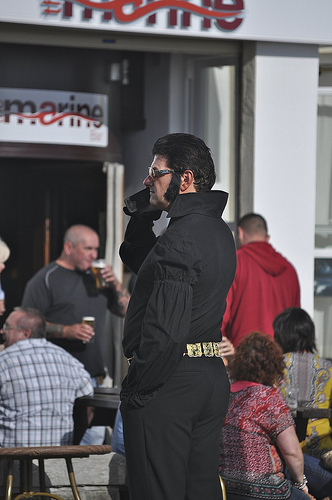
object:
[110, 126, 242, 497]
man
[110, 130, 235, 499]
elvis costume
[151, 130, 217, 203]
hair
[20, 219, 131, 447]
man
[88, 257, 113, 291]
beer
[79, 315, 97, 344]
beer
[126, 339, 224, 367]
belt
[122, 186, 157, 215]
cellphone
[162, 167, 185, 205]
sideburn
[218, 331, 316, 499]
woman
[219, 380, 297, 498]
shirt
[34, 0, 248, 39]
sign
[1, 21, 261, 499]
doorway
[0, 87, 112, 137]
sign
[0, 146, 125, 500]
doorway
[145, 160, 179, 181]
glasses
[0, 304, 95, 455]
man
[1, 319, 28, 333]
glasses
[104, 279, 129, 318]
forearm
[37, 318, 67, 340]
forearm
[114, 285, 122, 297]
tattoo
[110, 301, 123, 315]
tattoo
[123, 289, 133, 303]
tattoo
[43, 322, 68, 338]
tattoos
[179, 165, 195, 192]
ear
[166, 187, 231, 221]
collar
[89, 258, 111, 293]
glass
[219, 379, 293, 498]
print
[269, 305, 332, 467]
person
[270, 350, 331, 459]
shirt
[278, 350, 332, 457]
print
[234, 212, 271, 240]
buzz cut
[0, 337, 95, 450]
shirt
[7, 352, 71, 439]
plaid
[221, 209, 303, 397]
person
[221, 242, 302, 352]
hoodie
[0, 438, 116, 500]
furniture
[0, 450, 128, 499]
concrete block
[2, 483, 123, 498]
concrete block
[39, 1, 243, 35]
printing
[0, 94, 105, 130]
printing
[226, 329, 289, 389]
hair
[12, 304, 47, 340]
hair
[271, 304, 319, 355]
hair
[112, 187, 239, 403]
shirt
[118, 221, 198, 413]
sleeve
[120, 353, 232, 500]
pants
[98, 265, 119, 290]
hand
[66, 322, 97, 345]
hand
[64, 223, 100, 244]
bald spot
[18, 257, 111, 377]
shirt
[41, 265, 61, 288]
seam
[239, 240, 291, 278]
hood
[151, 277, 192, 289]
elastic@top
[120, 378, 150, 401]
elastic@wrist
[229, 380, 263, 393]
undershirt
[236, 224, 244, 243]
ear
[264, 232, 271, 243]
ear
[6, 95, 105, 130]
marine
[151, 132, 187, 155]
front